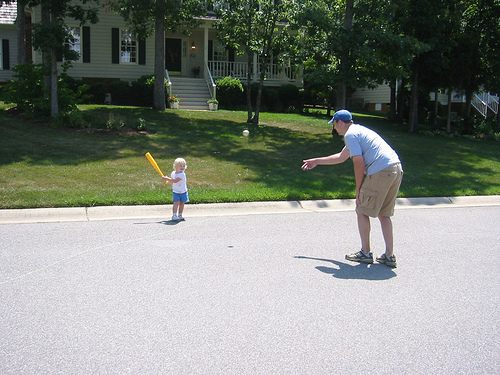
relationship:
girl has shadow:
[160, 158, 189, 221] [129, 211, 191, 229]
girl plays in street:
[160, 158, 189, 221] [12, 247, 295, 347]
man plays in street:
[300, 107, 404, 267] [12, 247, 295, 347]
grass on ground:
[2, 96, 494, 206] [2, 100, 493, 375]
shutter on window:
[224, 42, 241, 65] [61, 21, 84, 63]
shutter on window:
[129, 23, 156, 65] [61, 21, 84, 63]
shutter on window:
[110, 27, 122, 65] [61, 21, 84, 63]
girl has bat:
[160, 158, 189, 221] [143, 147, 168, 181]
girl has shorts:
[146, 149, 202, 224] [163, 183, 193, 208]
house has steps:
[1, 1, 304, 111] [163, 76, 217, 109]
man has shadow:
[300, 107, 404, 267] [298, 252, 414, 284]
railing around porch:
[208, 58, 298, 80] [165, 25, 301, 77]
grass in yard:
[0, 99, 500, 207] [5, 100, 494, 198]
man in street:
[300, 110, 402, 271] [2, 197, 497, 373]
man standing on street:
[300, 107, 404, 267] [2, 197, 497, 373]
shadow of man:
[290, 252, 400, 283] [300, 107, 404, 267]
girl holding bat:
[160, 158, 189, 221] [140, 146, 170, 183]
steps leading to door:
[164, 39, 211, 111] [162, 37, 188, 75]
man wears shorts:
[300, 107, 404, 267] [339, 165, 419, 222]